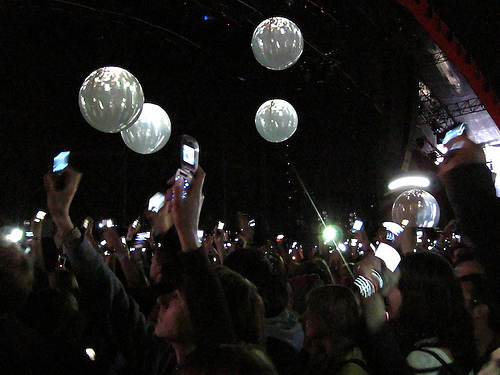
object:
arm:
[173, 227, 229, 349]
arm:
[352, 262, 389, 332]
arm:
[111, 249, 157, 308]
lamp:
[254, 98, 298, 143]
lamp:
[77, 66, 144, 134]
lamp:
[391, 188, 441, 229]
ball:
[77, 65, 143, 133]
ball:
[116, 102, 170, 155]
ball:
[391, 187, 441, 227]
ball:
[254, 99, 299, 143]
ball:
[251, 15, 305, 70]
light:
[318, 222, 343, 247]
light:
[386, 173, 430, 191]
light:
[2, 225, 24, 245]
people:
[2, 166, 499, 374]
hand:
[27, 217, 44, 233]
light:
[351, 219, 364, 232]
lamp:
[250, 17, 303, 71]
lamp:
[119, 100, 172, 155]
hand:
[81, 217, 97, 237]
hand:
[165, 165, 205, 225]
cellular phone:
[169, 135, 199, 201]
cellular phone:
[352, 219, 364, 231]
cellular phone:
[215, 221, 226, 230]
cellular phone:
[52, 150, 71, 184]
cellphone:
[97, 218, 114, 229]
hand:
[100, 227, 122, 250]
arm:
[442, 177, 499, 343]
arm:
[51, 221, 158, 355]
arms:
[214, 247, 229, 267]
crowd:
[0, 135, 499, 375]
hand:
[210, 229, 229, 244]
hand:
[41, 167, 84, 215]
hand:
[235, 228, 252, 244]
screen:
[53, 150, 70, 172]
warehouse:
[0, 0, 499, 375]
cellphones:
[246, 218, 255, 229]